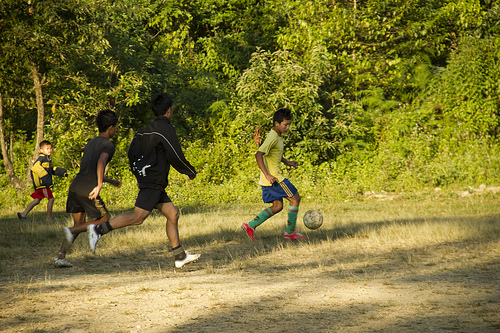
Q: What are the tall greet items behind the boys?
A: Trees.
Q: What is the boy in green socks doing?
A: Kicking a ball.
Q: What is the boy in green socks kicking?
A: A soccer ball.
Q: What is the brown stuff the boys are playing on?
A: Grass.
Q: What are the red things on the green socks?
A: Shoes.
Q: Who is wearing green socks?
A: A boy.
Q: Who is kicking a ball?
A: A boy.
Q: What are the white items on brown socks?
A: Shoes.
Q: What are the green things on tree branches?
A: Leaves.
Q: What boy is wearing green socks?
A: The one kicking the soccer ball.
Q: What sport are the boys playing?
A: Soccer.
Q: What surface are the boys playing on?
A: Grass and dirt.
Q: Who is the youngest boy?
A: The one on the left.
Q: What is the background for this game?
A: Green shrubbery.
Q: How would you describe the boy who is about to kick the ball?
A: He's the one in a yellow shirt and green socks.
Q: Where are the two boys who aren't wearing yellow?
A: In the middle.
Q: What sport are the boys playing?
A: Soccer.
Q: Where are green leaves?
A: On the trees.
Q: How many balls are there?
A: One.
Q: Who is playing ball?
A: Boys.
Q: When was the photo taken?
A: Day time.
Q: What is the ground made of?
A: Grass.